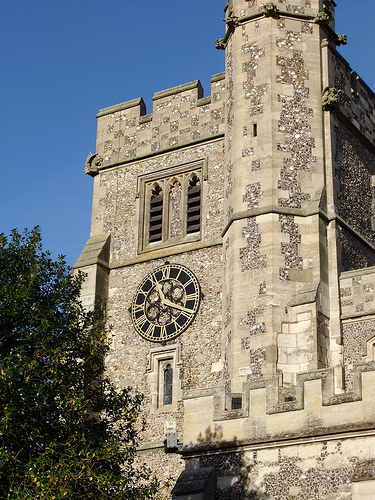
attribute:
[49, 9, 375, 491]
building — tower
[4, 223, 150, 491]
tree — tall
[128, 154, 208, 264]
window — closed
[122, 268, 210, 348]
clock — black, beige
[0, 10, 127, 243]
sky — blue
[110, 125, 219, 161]
surface — stone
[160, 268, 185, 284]
numerals — beige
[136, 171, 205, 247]
windows — arched